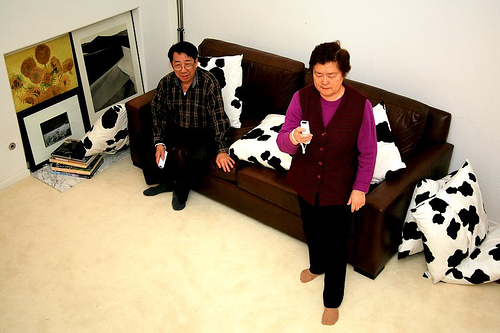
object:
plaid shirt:
[151, 66, 230, 152]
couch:
[124, 37, 452, 281]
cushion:
[236, 163, 301, 217]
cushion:
[205, 122, 248, 181]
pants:
[295, 193, 355, 308]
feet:
[321, 306, 338, 325]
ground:
[0, 217, 234, 333]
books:
[49, 138, 104, 180]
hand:
[290, 126, 313, 143]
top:
[275, 83, 376, 207]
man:
[275, 42, 374, 327]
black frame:
[3, 10, 133, 173]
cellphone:
[300, 120, 311, 144]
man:
[143, 41, 236, 210]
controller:
[158, 151, 168, 169]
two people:
[143, 41, 378, 325]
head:
[308, 40, 351, 96]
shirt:
[287, 84, 368, 205]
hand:
[347, 189, 366, 213]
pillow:
[366, 100, 406, 189]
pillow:
[196, 54, 242, 129]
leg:
[321, 210, 354, 325]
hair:
[308, 40, 351, 77]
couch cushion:
[304, 69, 428, 161]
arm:
[346, 98, 378, 213]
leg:
[299, 197, 327, 283]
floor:
[0, 160, 500, 333]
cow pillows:
[422, 225, 499, 286]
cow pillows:
[397, 170, 459, 260]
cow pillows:
[409, 159, 488, 284]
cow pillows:
[71, 103, 131, 159]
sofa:
[126, 38, 455, 280]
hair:
[168, 41, 199, 63]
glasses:
[173, 62, 196, 70]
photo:
[39, 111, 72, 148]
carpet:
[0, 143, 500, 333]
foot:
[300, 266, 320, 283]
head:
[168, 41, 197, 82]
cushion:
[228, 113, 292, 170]